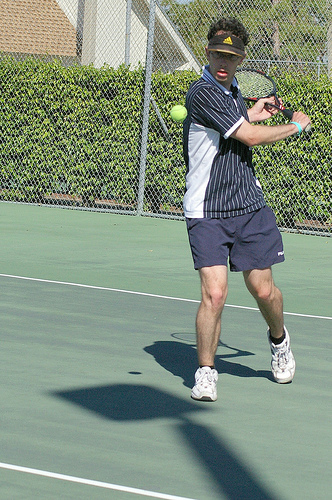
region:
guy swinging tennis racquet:
[166, 11, 329, 176]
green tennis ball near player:
[162, 6, 268, 172]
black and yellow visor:
[196, 19, 273, 68]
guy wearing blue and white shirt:
[191, 14, 264, 216]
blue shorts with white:
[179, 199, 286, 280]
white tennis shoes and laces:
[174, 336, 321, 412]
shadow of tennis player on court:
[126, 312, 296, 431]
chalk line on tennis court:
[14, 450, 126, 497]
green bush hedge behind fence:
[24, 58, 202, 187]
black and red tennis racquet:
[214, 64, 298, 131]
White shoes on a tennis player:
[179, 325, 307, 406]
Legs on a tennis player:
[175, 247, 307, 398]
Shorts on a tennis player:
[179, 193, 287, 277]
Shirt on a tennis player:
[167, 71, 265, 211]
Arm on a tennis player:
[233, 104, 313, 167]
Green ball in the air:
[148, 91, 213, 145]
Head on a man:
[201, 15, 249, 85]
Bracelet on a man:
[282, 106, 312, 142]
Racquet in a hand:
[222, 59, 315, 155]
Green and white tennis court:
[26, 238, 169, 405]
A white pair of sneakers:
[189, 358, 233, 415]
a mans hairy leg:
[193, 265, 238, 373]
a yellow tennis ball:
[157, 93, 201, 136]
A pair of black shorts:
[182, 193, 305, 283]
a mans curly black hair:
[207, 8, 256, 47]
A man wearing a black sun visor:
[197, 13, 265, 75]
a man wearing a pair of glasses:
[205, 47, 248, 70]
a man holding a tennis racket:
[243, 52, 298, 143]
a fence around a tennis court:
[134, 19, 176, 217]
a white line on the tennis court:
[67, 263, 176, 317]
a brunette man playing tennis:
[182, 13, 305, 405]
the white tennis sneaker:
[192, 367, 220, 404]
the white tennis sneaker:
[266, 326, 293, 380]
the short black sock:
[198, 362, 213, 369]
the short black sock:
[267, 327, 285, 343]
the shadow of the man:
[145, 336, 283, 397]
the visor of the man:
[205, 34, 244, 51]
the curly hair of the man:
[208, 15, 250, 39]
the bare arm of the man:
[231, 111, 298, 150]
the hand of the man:
[293, 110, 311, 127]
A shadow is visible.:
[194, 438, 216, 461]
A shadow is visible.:
[205, 432, 227, 490]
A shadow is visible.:
[215, 403, 261, 498]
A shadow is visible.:
[191, 399, 238, 498]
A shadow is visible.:
[229, 417, 252, 490]